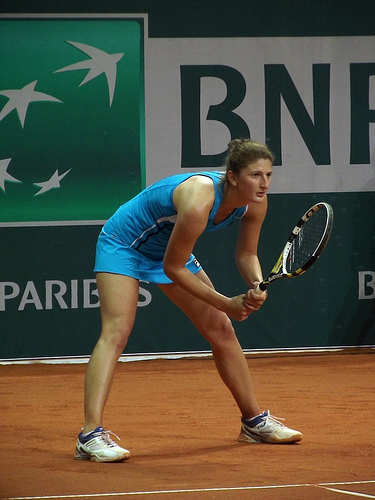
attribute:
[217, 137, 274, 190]
hair — tight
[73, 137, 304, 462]
person — playing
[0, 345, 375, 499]
tennis court — red, white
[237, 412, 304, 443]
shoe — white, blue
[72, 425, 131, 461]
shoe — white, blue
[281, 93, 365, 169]
wall — dark green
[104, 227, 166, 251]
tag — black